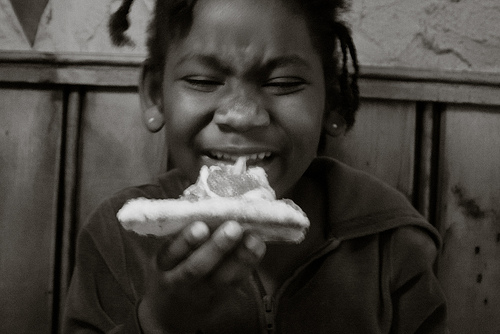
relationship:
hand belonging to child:
[139, 219, 268, 332] [57, 0, 450, 330]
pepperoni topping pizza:
[205, 165, 259, 198] [113, 159, 309, 248]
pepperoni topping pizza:
[174, 183, 211, 200] [113, 159, 309, 248]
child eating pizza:
[57, 0, 450, 330] [115, 156, 311, 246]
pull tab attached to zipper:
[260, 290, 278, 331] [252, 237, 336, 332]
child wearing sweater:
[57, 0, 450, 330] [60, 155, 448, 333]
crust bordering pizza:
[117, 196, 310, 243] [115, 156, 311, 246]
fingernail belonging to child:
[188, 220, 208, 238] [57, 0, 450, 330]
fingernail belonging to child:
[221, 218, 243, 239] [57, 0, 450, 330]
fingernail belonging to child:
[243, 232, 259, 250] [57, 0, 450, 330]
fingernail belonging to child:
[252, 239, 266, 257] [57, 0, 450, 330]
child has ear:
[57, 0, 450, 330] [138, 56, 165, 132]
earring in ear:
[144, 115, 157, 131] [138, 56, 165, 132]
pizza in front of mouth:
[115, 156, 311, 243] [198, 146, 277, 172]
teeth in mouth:
[209, 149, 269, 159] [197, 141, 281, 172]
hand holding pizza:
[139, 219, 268, 332] [115, 156, 311, 243]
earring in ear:
[328, 122, 340, 136] [327, 68, 350, 147]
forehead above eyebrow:
[189, 3, 312, 66] [174, 48, 236, 77]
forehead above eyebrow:
[189, 3, 312, 66] [258, 51, 310, 75]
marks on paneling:
[444, 179, 493, 285] [0, 51, 498, 331]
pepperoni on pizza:
[205, 165, 262, 198] [115, 156, 311, 243]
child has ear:
[57, 0, 450, 330] [321, 66, 354, 136]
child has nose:
[57, 0, 450, 330] [214, 85, 273, 134]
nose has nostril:
[214, 85, 273, 134] [218, 124, 237, 134]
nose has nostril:
[214, 85, 273, 134] [250, 124, 263, 132]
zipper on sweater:
[241, 236, 341, 332] [60, 155, 448, 333]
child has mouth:
[57, 0, 450, 330] [197, 141, 281, 172]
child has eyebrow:
[57, 0, 450, 330] [173, 49, 237, 75]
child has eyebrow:
[57, 0, 450, 330] [256, 51, 311, 81]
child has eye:
[57, 0, 450, 330] [178, 70, 223, 91]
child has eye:
[57, 0, 450, 330] [262, 69, 307, 96]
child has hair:
[57, 0, 450, 330] [106, 0, 363, 136]